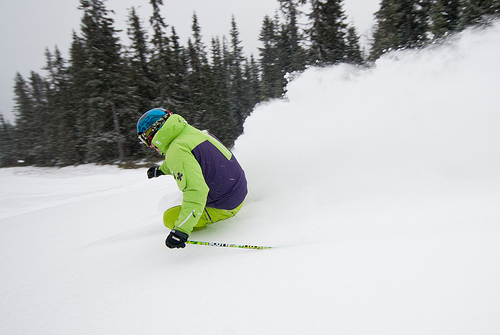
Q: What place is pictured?
A: It is a field.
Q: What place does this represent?
A: It represents the field.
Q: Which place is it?
A: It is a field.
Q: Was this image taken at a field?
A: Yes, it was taken in a field.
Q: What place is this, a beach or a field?
A: It is a field.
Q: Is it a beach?
A: No, it is a field.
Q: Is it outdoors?
A: Yes, it is outdoors.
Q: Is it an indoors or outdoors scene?
A: It is outdoors.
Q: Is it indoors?
A: No, it is outdoors.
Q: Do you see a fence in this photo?
A: No, there are no fences.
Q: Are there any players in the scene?
A: No, there are no players.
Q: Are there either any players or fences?
A: No, there are no players or fences.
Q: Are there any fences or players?
A: No, there are no players or fences.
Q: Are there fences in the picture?
A: No, there are no fences.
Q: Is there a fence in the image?
A: No, there are no fences.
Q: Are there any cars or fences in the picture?
A: No, there are no fences or cars.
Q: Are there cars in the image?
A: No, there are no cars.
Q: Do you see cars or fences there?
A: No, there are no cars or fences.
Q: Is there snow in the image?
A: Yes, there is snow.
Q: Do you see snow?
A: Yes, there is snow.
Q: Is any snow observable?
A: Yes, there is snow.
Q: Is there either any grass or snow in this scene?
A: Yes, there is snow.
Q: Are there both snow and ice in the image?
A: No, there is snow but no ice.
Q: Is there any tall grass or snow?
A: Yes, there is tall snow.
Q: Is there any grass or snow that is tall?
A: Yes, the snow is tall.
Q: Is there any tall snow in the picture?
A: Yes, there is tall snow.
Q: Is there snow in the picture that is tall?
A: Yes, there is tall snow.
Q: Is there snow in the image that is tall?
A: Yes, there is snow that is tall.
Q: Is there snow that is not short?
A: Yes, there is tall snow.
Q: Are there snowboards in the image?
A: No, there are no snowboards.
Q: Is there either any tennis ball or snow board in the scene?
A: No, there are no snowboards or tennis balls.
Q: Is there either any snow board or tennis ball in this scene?
A: No, there are no snowboards or tennis balls.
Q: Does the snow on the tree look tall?
A: Yes, the snow is tall.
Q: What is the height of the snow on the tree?
A: The snow is tall.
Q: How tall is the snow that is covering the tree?
A: The snow is tall.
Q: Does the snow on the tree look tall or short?
A: The snow is tall.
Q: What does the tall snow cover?
A: The snow covers the tree.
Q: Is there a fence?
A: No, there are no fences.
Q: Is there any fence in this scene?
A: No, there are no fences.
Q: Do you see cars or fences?
A: No, there are no fences or cars.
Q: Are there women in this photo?
A: No, there are no women.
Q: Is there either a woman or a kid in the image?
A: No, there are no women or children.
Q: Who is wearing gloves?
A: The man is wearing gloves.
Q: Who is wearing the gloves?
A: The man is wearing gloves.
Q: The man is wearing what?
A: The man is wearing gloves.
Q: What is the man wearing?
A: The man is wearing gloves.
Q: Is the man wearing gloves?
A: Yes, the man is wearing gloves.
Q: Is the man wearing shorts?
A: No, the man is wearing gloves.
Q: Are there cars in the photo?
A: No, there are no cars.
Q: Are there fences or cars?
A: No, there are no cars or fences.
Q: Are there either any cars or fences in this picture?
A: No, there are no fences or cars.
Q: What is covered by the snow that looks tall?
A: The tree is covered by the snow.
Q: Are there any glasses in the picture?
A: No, there are no glasses.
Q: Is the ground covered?
A: Yes, the ground is covered.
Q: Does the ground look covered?
A: Yes, the ground is covered.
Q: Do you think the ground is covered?
A: Yes, the ground is covered.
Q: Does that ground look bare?
A: No, the ground is covered.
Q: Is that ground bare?
A: No, the ground is covered.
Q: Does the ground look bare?
A: No, the ground is covered.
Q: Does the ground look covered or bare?
A: The ground is covered.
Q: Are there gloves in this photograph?
A: Yes, there are gloves.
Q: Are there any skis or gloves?
A: Yes, there are gloves.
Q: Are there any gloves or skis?
A: Yes, there are gloves.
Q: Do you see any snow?
A: Yes, there is snow.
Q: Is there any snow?
A: Yes, there is snow.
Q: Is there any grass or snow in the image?
A: Yes, there is snow.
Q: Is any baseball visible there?
A: No, there are no baseballs.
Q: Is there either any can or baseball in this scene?
A: No, there are no baseballs or cans.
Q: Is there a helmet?
A: Yes, there is a helmet.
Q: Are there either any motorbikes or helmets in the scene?
A: Yes, there is a helmet.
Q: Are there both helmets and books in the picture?
A: No, there is a helmet but no books.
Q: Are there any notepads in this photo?
A: No, there are no notepads.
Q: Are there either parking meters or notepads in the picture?
A: No, there are no notepads or parking meters.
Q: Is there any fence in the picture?
A: No, there are no fences.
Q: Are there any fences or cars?
A: No, there are no fences or cars.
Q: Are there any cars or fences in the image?
A: No, there are no fences or cars.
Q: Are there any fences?
A: No, there are no fences.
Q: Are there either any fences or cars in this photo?
A: No, there are no fences or cars.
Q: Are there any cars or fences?
A: No, there are no fences or cars.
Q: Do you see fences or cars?
A: No, there are no fences or cars.